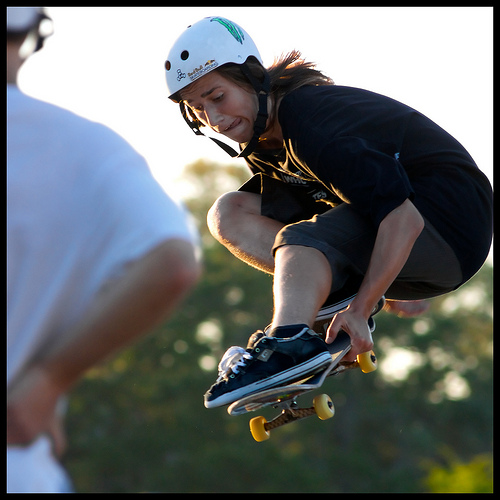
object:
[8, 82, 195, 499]
shirt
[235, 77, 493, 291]
black shirt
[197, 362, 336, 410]
sole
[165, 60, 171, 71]
hole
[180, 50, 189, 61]
hole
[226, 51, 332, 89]
hair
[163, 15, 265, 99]
helmet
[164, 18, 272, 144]
head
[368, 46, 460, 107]
wood chips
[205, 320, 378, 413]
board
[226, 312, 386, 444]
skate board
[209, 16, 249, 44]
design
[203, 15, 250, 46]
green logo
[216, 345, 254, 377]
laces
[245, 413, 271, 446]
stromboli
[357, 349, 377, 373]
wheel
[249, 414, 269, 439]
wheel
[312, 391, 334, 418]
wheel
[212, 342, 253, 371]
shoelaces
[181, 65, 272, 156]
strap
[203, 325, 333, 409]
shoe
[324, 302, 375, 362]
hand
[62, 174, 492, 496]
trees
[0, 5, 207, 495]
person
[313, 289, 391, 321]
foot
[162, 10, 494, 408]
man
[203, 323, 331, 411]
feet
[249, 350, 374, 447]
trucks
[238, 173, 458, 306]
shorts